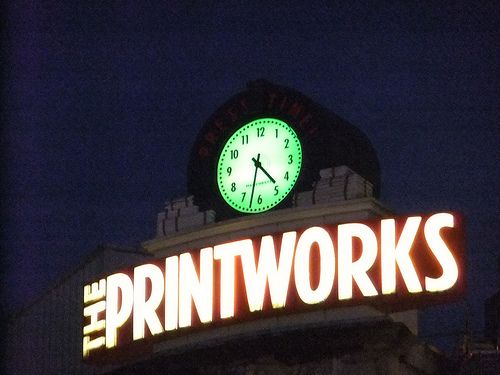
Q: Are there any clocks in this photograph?
A: Yes, there is a clock.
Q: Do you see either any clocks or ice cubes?
A: Yes, there is a clock.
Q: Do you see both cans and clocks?
A: No, there is a clock but no cans.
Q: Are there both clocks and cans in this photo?
A: No, there is a clock but no cans.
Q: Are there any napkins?
A: No, there are no napkins.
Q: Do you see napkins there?
A: No, there are no napkins.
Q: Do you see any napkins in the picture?
A: No, there are no napkins.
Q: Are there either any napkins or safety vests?
A: No, there are no napkins or safety vests.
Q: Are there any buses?
A: No, there are no buses.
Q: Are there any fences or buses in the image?
A: No, there are no buses or fences.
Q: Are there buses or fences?
A: No, there are no buses or fences.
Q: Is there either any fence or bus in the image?
A: No, there are no buses or fences.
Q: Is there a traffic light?
A: No, there are no traffic lights.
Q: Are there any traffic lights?
A: No, there are no traffic lights.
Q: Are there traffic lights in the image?
A: No, there are no traffic lights.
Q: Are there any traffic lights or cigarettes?
A: No, there are no traffic lights or cigarettes.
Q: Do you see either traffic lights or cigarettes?
A: No, there are no traffic lights or cigarettes.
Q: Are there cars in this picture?
A: No, there are no cars.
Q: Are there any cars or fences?
A: No, there are no cars or fences.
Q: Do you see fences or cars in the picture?
A: No, there are no cars or fences.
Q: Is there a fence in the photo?
A: No, there are no fences.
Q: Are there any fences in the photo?
A: No, there are no fences.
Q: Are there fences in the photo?
A: No, there are no fences.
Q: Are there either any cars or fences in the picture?
A: No, there are no fences or cars.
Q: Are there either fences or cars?
A: No, there are no fences or cars.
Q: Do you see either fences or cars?
A: No, there are no fences or cars.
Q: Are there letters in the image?
A: Yes, there are letters.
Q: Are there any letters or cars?
A: Yes, there are letters.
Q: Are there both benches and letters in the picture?
A: No, there are letters but no benches.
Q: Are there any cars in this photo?
A: No, there are no cars.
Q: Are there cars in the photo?
A: No, there are no cars.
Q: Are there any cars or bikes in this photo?
A: No, there are no cars or bikes.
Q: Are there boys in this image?
A: No, there are no boys.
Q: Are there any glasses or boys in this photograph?
A: No, there are no boys or glasses.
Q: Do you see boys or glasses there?
A: No, there are no boys or glasses.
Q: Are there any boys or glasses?
A: No, there are no boys or glasses.